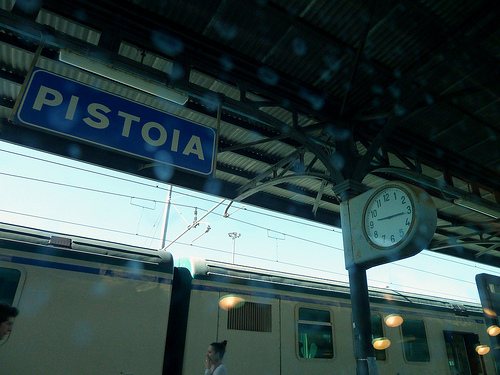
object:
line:
[133, 265, 180, 304]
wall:
[94, 252, 179, 339]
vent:
[227, 299, 273, 334]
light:
[453, 197, 498, 221]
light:
[51, 47, 186, 106]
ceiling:
[1, 1, 496, 267]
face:
[307, 329, 335, 351]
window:
[397, 314, 435, 366]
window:
[0, 259, 26, 344]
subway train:
[0, 220, 500, 375]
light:
[225, 231, 244, 264]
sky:
[164, 264, 341, 373]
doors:
[440, 331, 489, 373]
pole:
[348, 266, 373, 373]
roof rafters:
[3, 2, 498, 262]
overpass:
[0, 0, 497, 267]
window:
[292, 300, 336, 360]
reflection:
[200, 279, 497, 369]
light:
[382, 312, 406, 328]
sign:
[12, 69, 218, 179]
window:
[146, 102, 324, 281]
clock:
[359, 182, 414, 248]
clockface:
[364, 186, 413, 246]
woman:
[201, 336, 236, 375]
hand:
[203, 353, 212, 368]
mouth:
[208, 353, 213, 361]